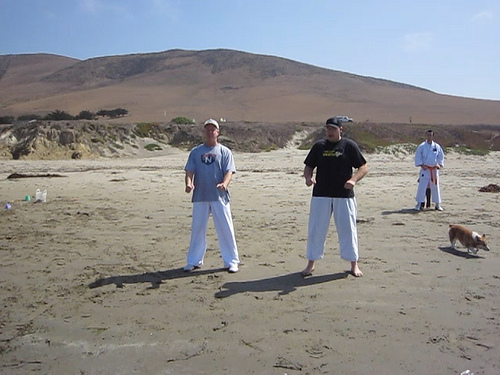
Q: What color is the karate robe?
A: White.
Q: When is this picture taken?
A: Daytime.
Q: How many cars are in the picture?
A: One.